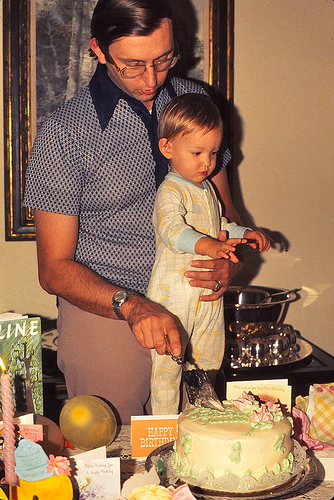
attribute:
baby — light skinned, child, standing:
[144, 92, 272, 416]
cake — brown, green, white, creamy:
[172, 391, 295, 491]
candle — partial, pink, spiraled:
[0, 359, 18, 499]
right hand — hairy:
[126, 298, 181, 361]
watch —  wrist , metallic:
[110, 288, 142, 321]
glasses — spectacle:
[105, 35, 182, 78]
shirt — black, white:
[21, 60, 233, 297]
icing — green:
[195, 402, 247, 425]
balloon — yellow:
[57, 393, 118, 453]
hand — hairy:
[185, 255, 241, 302]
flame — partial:
[0, 356, 7, 376]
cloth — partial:
[297, 380, 333, 444]